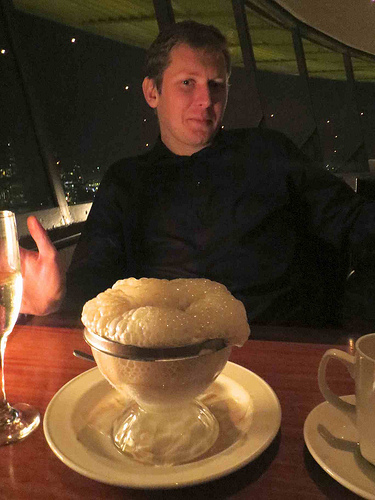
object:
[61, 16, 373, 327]
man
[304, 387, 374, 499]
plate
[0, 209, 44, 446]
glass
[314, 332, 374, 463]
cup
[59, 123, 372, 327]
shirt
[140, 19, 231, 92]
hair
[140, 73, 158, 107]
ear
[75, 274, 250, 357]
foam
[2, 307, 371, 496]
table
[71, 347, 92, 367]
spoon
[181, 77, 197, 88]
eye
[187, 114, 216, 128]
mouth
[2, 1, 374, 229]
window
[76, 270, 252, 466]
dessert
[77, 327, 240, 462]
bowl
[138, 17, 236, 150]
head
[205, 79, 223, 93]
eye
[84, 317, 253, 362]
rim